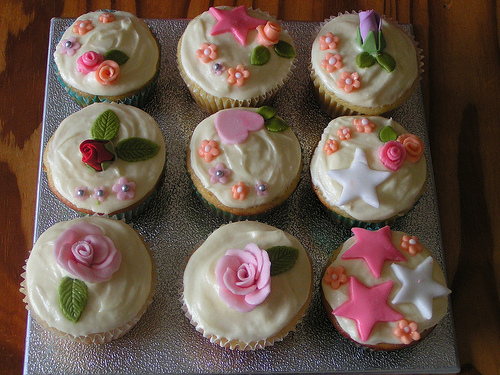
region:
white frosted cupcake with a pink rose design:
[18, 211, 159, 346]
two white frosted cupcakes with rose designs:
[17, 210, 319, 353]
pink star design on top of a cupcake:
[339, 222, 411, 279]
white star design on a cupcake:
[384, 254, 454, 321]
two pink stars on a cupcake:
[328, 222, 407, 342]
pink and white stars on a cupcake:
[320, 221, 456, 353]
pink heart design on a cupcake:
[212, 106, 266, 146]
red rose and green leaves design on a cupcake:
[78, 107, 163, 176]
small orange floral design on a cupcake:
[227, 180, 253, 199]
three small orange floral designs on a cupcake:
[313, 30, 363, 94]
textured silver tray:
[26, 16, 461, 373]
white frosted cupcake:
[24, 213, 154, 344]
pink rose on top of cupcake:
[51, 221, 121, 283]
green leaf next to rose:
[59, 277, 90, 322]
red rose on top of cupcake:
[79, 138, 114, 168]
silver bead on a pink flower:
[76, 190, 83, 196]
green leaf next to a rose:
[90, 107, 122, 142]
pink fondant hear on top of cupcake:
[213, 107, 267, 145]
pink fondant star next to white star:
[334, 278, 401, 341]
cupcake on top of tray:
[178, 218, 318, 350]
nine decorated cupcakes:
[19, 8, 449, 346]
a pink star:
[334, 278, 396, 340]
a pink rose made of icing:
[216, 240, 298, 313]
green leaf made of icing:
[56, 275, 85, 322]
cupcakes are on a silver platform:
[26, 17, 457, 374]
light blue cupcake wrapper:
[53, 63, 158, 111]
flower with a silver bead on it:
[254, 180, 267, 195]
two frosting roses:
[76, 48, 127, 83]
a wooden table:
[3, 2, 497, 357]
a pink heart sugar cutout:
[216, 107, 264, 143]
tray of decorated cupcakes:
[17, 1, 476, 374]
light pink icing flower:
[209, 236, 297, 314]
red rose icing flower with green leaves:
[78, 108, 163, 178]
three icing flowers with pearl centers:
[69, 174, 140, 205]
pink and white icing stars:
[330, 228, 453, 343]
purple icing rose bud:
[354, 9, 399, 79]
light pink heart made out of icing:
[212, 106, 266, 144]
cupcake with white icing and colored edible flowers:
[54, 6, 166, 106]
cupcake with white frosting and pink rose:
[184, 217, 313, 355]